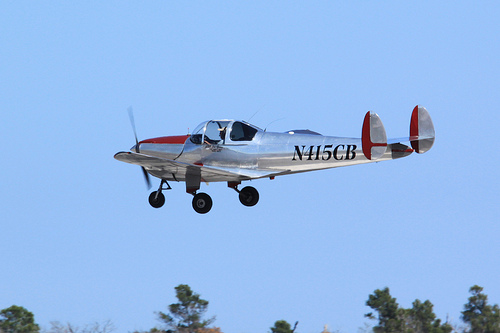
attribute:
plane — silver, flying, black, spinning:
[94, 89, 464, 250]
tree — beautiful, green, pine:
[391, 290, 449, 330]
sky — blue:
[187, 17, 259, 51]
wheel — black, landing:
[221, 184, 297, 213]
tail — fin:
[340, 90, 443, 160]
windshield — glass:
[177, 115, 221, 156]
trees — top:
[151, 282, 219, 320]